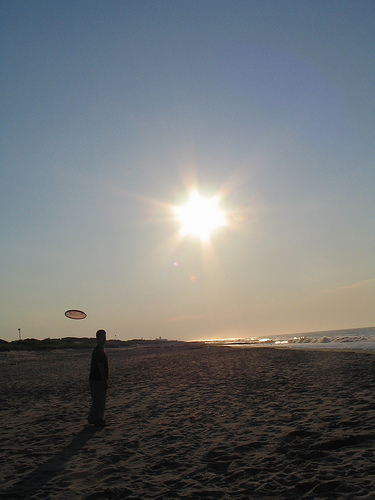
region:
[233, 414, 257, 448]
part fo a ground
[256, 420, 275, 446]
aprt of a sand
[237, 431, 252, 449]
part of a gronjd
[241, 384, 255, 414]
part of a grund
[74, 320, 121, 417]
this is a boy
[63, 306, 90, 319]
this is a frisbee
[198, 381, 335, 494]
this is the beach sand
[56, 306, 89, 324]
the frisbee is on air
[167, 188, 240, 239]
this is the sun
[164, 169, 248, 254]
the sun is bright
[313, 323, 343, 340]
this is the sea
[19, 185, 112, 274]
this is the sky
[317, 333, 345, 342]
these are the waves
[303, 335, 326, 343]
the waves are strong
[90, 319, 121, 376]
the head of a man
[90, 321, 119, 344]
the face of a man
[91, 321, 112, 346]
the hair of a man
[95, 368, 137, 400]
the hand of a man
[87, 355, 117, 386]
the arm of a man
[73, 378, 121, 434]
the leg of a man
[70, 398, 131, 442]
the feet of a man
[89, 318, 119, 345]
the chin of a man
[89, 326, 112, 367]
the ear of a man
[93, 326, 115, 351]
the nose of a man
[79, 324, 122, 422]
this is a man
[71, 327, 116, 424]
the man is throwing a frisbee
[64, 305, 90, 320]
the frisbee is on air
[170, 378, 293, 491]
this is the beach sand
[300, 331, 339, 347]
this is the sea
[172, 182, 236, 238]
this is the sun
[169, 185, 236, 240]
the sun is shining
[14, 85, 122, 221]
this is the sky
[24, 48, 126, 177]
the sky is clear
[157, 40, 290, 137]
the sky is blue in color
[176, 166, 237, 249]
this is the sun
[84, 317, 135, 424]
this is a man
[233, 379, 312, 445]
the sand is brown in color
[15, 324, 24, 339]
this is a pole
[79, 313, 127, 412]
the man is standing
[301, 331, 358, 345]
this is a water body